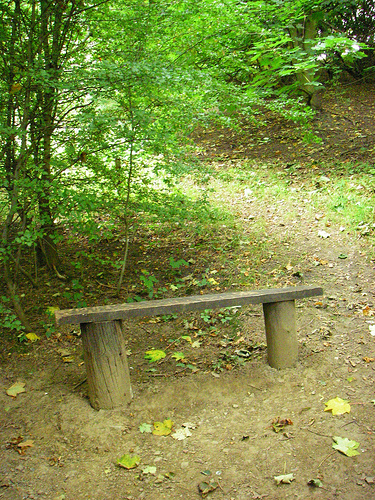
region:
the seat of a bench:
[51, 279, 329, 331]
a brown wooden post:
[77, 315, 137, 414]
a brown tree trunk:
[31, 63, 71, 271]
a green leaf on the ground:
[111, 447, 146, 470]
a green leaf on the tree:
[300, 75, 320, 85]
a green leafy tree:
[0, 0, 367, 288]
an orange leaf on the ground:
[15, 435, 37, 450]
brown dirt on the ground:
[0, 351, 368, 497]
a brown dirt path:
[167, 167, 374, 359]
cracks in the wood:
[99, 335, 119, 401]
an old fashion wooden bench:
[55, 282, 323, 409]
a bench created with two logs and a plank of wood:
[55, 282, 323, 410]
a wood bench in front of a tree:
[55, 283, 325, 412]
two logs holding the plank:
[80, 301, 295, 409]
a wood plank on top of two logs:
[54, 283, 324, 324]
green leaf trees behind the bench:
[1, 1, 319, 284]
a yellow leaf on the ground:
[322, 397, 363, 416]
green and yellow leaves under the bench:
[143, 335, 186, 361]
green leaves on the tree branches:
[84, 0, 324, 226]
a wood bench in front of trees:
[7, 33, 324, 408]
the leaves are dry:
[206, 480, 215, 496]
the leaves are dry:
[201, 481, 211, 497]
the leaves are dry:
[203, 480, 213, 490]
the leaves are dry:
[205, 476, 213, 485]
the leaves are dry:
[205, 480, 210, 497]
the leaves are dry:
[199, 475, 211, 493]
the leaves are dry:
[202, 484, 208, 493]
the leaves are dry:
[205, 488, 210, 492]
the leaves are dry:
[202, 487, 207, 489]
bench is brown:
[71, 257, 349, 398]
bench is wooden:
[55, 241, 310, 430]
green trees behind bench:
[6, 50, 188, 299]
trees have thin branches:
[36, 6, 154, 284]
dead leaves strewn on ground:
[60, 313, 266, 461]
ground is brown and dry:
[125, 360, 317, 489]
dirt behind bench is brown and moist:
[243, 90, 368, 173]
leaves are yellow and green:
[291, 387, 360, 487]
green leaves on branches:
[224, 23, 355, 100]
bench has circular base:
[74, 307, 135, 417]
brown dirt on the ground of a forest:
[182, 399, 241, 437]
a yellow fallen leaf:
[319, 398, 353, 420]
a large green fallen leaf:
[141, 340, 172, 369]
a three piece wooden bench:
[38, 273, 328, 409]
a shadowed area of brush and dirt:
[317, 107, 362, 161]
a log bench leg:
[86, 320, 135, 415]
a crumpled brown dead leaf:
[272, 408, 293, 435]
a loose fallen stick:
[122, 109, 137, 301]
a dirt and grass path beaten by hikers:
[196, 178, 369, 285]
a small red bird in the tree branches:
[94, 54, 103, 63]